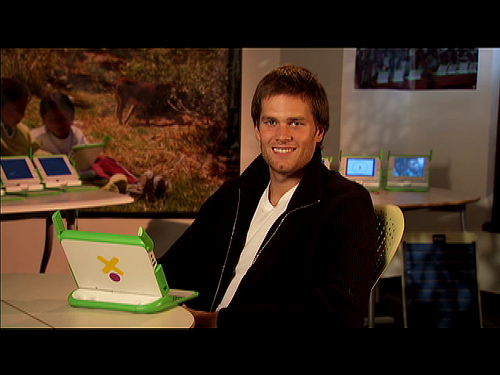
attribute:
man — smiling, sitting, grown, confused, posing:
[178, 66, 372, 375]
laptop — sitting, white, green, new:
[53, 206, 197, 314]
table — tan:
[4, 218, 197, 334]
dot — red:
[110, 274, 121, 283]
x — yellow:
[100, 258, 124, 276]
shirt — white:
[216, 179, 302, 306]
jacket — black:
[157, 148, 375, 373]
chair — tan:
[368, 203, 403, 309]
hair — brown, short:
[251, 68, 331, 122]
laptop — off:
[0, 151, 38, 197]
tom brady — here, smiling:
[192, 66, 377, 375]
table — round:
[363, 190, 478, 203]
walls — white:
[0, 44, 498, 232]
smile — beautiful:
[269, 143, 300, 153]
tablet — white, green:
[46, 212, 200, 315]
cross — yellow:
[96, 255, 124, 271]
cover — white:
[73, 241, 154, 296]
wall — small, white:
[242, 49, 337, 165]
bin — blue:
[404, 240, 484, 326]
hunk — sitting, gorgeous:
[203, 67, 363, 331]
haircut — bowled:
[249, 69, 332, 129]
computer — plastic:
[64, 230, 196, 314]